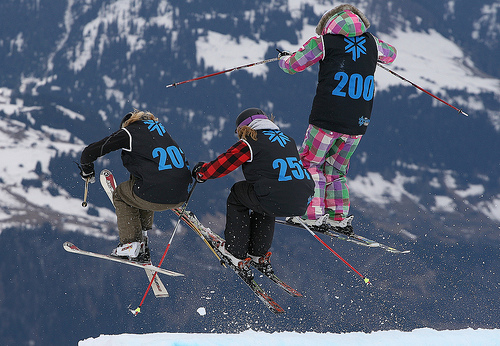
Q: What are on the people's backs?
A: Numbers.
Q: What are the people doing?
A: Skiing.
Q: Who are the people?
A: Skiers.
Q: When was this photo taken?
A: During the day.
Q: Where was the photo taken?
A: On a mountain.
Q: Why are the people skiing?
A: To have fun.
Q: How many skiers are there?
A: 3.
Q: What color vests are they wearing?
A: Black and blue.